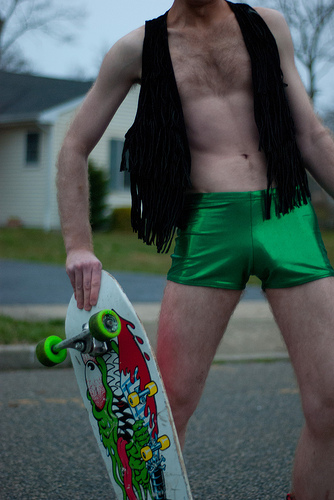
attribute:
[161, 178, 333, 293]
shorts — green, short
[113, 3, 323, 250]
vest — black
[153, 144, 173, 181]
vest — black